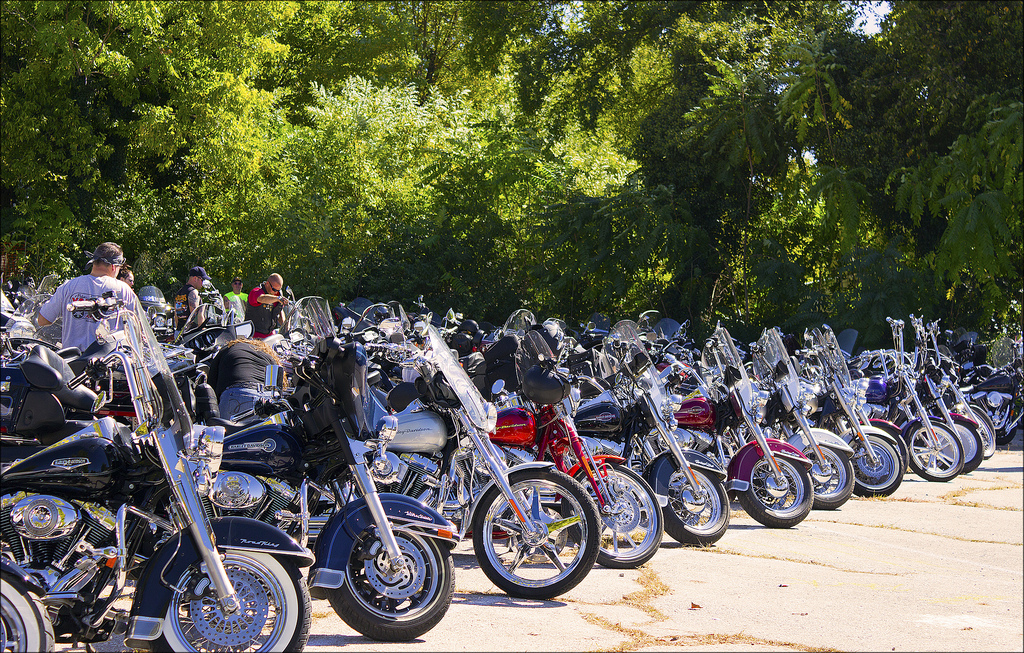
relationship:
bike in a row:
[232, 324, 412, 612] [404, 290, 791, 514]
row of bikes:
[404, 290, 791, 514] [3, 303, 286, 469]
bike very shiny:
[232, 324, 412, 612] [100, 421, 221, 482]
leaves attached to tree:
[141, 20, 261, 78] [627, 237, 710, 309]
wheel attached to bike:
[434, 433, 585, 578] [232, 324, 412, 612]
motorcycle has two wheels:
[392, 311, 582, 532] [615, 444, 801, 520]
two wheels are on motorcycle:
[615, 444, 801, 520] [392, 311, 582, 532]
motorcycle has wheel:
[392, 311, 582, 532] [434, 433, 585, 578]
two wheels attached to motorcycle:
[615, 444, 801, 520] [392, 311, 582, 532]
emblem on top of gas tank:
[30, 504, 59, 528] [5, 506, 91, 539]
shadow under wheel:
[451, 586, 525, 606] [434, 433, 585, 578]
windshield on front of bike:
[112, 321, 153, 411] [232, 324, 412, 612]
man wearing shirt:
[25, 248, 128, 363] [63, 283, 101, 308]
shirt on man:
[63, 283, 101, 308] [25, 248, 128, 363]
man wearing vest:
[25, 248, 128, 363] [247, 305, 279, 335]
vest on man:
[247, 305, 279, 335] [25, 248, 128, 363]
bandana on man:
[188, 267, 205, 278] [25, 248, 128, 363]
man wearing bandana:
[25, 248, 128, 363] [188, 267, 205, 278]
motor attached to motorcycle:
[355, 400, 448, 437] [392, 311, 582, 532]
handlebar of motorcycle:
[345, 348, 469, 401] [392, 311, 582, 532]